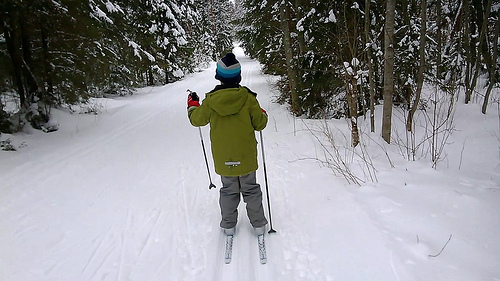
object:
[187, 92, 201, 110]
glove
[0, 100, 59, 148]
snow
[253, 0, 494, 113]
bushes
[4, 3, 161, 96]
bushes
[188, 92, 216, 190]
pole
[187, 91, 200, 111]
hand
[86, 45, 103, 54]
green leaves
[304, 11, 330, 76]
green leaves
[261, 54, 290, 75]
green leaves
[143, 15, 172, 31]
green leaves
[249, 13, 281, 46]
green leaves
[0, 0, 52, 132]
tree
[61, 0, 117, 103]
tree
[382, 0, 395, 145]
tree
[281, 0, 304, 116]
tree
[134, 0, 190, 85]
tree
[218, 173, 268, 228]
boy's pants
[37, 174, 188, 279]
snow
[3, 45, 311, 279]
road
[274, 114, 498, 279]
snow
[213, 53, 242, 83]
hat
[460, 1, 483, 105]
tree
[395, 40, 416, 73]
leaves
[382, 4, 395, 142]
tree trunk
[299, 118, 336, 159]
twigs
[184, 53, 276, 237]
boy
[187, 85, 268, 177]
hoodie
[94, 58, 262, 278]
snow passage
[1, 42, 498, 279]
ground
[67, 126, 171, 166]
snow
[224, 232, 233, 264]
ski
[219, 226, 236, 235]
foot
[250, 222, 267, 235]
foot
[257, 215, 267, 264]
ski